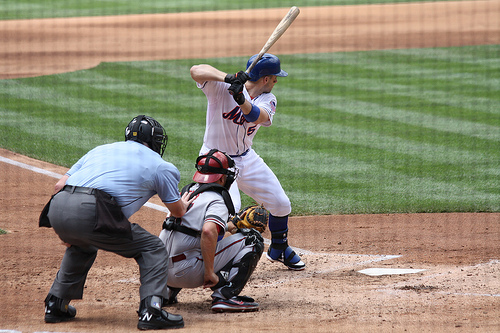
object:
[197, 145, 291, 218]
pants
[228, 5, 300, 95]
bat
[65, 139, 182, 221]
blue shirt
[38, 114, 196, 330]
umpire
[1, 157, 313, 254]
foul line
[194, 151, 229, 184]
baseball helmet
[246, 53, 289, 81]
baseball helmet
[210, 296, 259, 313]
baseball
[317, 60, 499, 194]
grass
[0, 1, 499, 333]
field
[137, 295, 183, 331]
umpire's shoe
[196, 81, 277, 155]
shirt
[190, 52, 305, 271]
batter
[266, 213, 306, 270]
shoes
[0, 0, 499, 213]
infield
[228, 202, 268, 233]
cleat